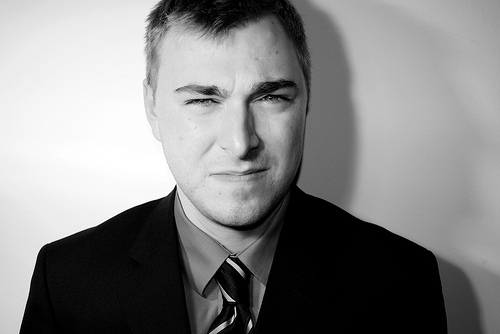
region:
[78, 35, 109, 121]
The wall is white.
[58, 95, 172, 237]
The wall is white.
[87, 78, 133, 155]
The wall is white.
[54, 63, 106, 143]
The wall is white.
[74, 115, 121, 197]
The wall is white.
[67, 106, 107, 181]
The wall is white.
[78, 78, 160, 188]
The wall is white.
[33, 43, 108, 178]
The wall is white.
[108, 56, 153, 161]
The wall is white.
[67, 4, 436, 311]
man in black and white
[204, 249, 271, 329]
striped tie on man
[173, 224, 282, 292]
collar of dress shirt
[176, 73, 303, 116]
squinted eyes of man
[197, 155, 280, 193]
closed lips on man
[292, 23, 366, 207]
shadow of man on wall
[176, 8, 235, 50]
short hair over forehead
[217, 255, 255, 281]
white stripe on tie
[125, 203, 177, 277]
lapel on man's jacket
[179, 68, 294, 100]
eyebrows on man's forehead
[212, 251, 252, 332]
tie is complete and straight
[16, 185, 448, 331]
black coat being sported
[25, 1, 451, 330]
man in a suit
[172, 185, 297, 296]
collar from inside shirt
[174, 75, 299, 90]
eyebrows of man taking photo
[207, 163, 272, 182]
mouth of individual male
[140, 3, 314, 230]
head shot for portfolio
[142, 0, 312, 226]
photo for an id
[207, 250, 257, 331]
my stripe design tie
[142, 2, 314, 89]
latest hair due fro barber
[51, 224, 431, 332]
the coat is black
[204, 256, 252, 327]
the tie is striped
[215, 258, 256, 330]
the stripes are white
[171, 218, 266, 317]
the shirt is grey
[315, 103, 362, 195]
the shadow is black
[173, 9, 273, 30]
the hair is black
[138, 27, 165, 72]
the hair is white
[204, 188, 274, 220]
the chin has no beards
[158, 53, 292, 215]
the face has no smile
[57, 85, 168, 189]
there is light reflection on wall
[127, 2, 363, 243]
man with a concerned look on face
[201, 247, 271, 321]
tie knot around a man's neck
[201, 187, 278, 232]
white chin with stubble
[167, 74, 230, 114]
squinted eye with eyebrow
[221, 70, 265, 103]
frown lines on forehead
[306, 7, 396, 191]
shadow of man's head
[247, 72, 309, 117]
eye squinted in concern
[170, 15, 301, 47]
receding hairline on a man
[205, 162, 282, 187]
tightened lips of a man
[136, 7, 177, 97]
spiky hair of a man